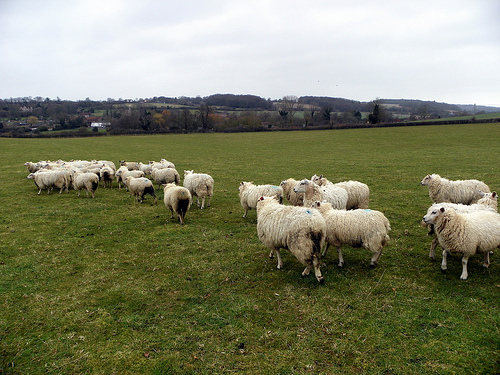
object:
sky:
[0, 0, 498, 107]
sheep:
[254, 192, 328, 283]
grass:
[0, 113, 499, 374]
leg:
[457, 251, 471, 279]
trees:
[274, 95, 303, 120]